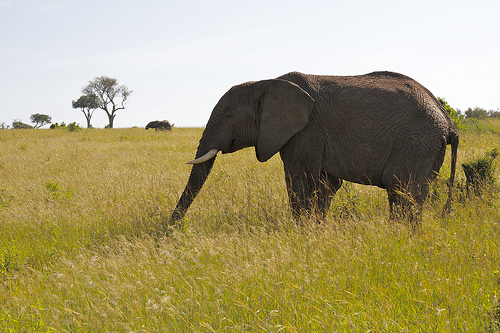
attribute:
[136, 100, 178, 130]
animal — dark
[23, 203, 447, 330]
grass — green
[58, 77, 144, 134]
trees — tall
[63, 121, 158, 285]
field — grassy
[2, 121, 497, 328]
grass — tall, green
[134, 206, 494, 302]
grass — green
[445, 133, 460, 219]
tail — long and gray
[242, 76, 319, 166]
gray ear — large and gray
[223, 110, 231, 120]
eye — small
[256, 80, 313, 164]
ear — large and gray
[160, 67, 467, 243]
elephant — gray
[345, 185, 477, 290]
grass — tall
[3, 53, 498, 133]
sky — light, blue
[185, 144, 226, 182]
tusk — white, ivory